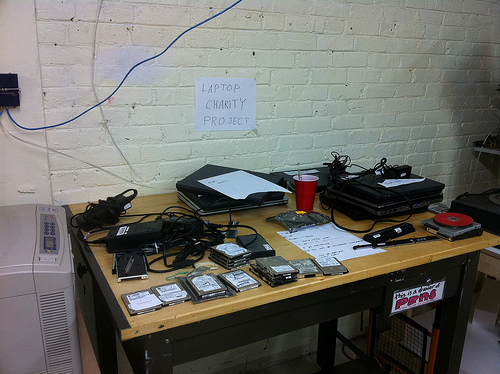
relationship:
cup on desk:
[289, 173, 321, 212] [57, 191, 498, 374]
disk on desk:
[142, 283, 187, 305] [191, 303, 211, 318]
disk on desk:
[222, 262, 257, 293] [62, 162, 498, 372]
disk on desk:
[118, 288, 166, 317] [62, 162, 498, 372]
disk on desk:
[216, 268, 257, 294] [62, 162, 498, 372]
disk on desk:
[289, 256, 322, 280] [62, 162, 498, 372]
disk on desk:
[309, 252, 348, 277] [62, 162, 498, 372]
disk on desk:
[216, 241, 252, 270] [86, 187, 486, 282]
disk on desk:
[259, 263, 291, 280] [178, 207, 453, 266]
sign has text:
[182, 63, 305, 155] [179, 68, 281, 153]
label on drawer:
[391, 281, 444, 312] [385, 264, 466, 321]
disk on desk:
[278, 242, 374, 302] [63, 104, 484, 367]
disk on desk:
[431, 201, 492, 235] [217, 134, 487, 319]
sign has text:
[193, 77, 258, 133] [202, 83, 249, 129]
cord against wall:
[23, 55, 128, 130] [7, 2, 497, 219]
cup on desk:
[291, 170, 318, 215] [62, 162, 498, 372]